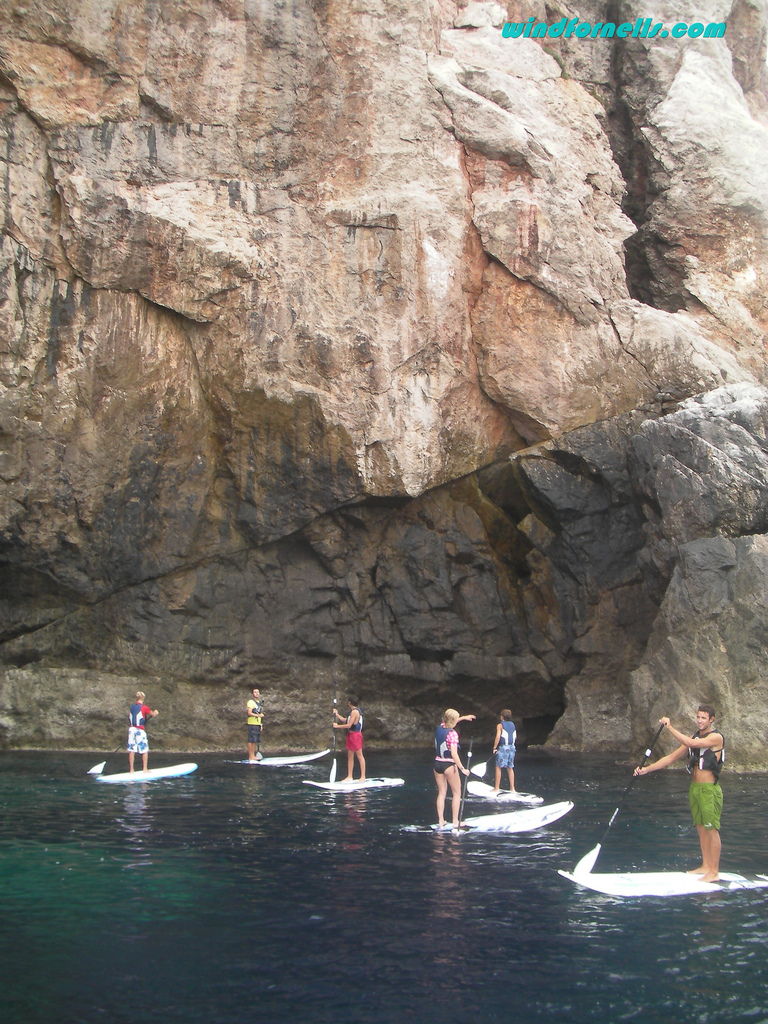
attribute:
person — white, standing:
[432, 707, 474, 830]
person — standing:
[489, 708, 517, 790]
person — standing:
[639, 701, 732, 877]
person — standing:
[333, 705, 370, 779]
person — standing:
[237, 676, 258, 761]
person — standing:
[120, 690, 152, 770]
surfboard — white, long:
[99, 746, 197, 794]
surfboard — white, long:
[243, 740, 329, 766]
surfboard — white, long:
[303, 771, 400, 792]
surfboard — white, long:
[413, 798, 573, 839]